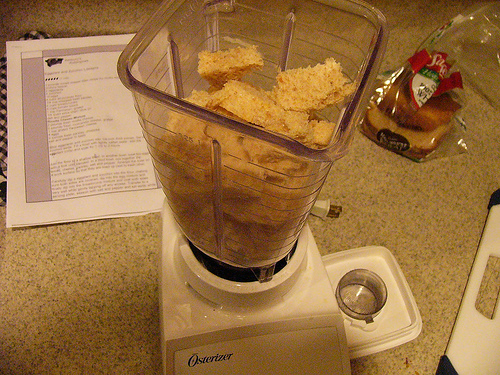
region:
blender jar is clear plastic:
[118, 1, 393, 282]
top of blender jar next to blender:
[319, 243, 424, 361]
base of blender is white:
[158, 196, 352, 373]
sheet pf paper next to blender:
[4, 32, 169, 228]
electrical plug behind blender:
[311, 199, 344, 223]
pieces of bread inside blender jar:
[163, 44, 360, 146]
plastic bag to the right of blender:
[358, 10, 495, 159]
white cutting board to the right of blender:
[432, 186, 499, 373]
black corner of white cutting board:
[432, 355, 455, 374]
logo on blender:
[184, 350, 237, 367]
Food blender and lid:
[141, 209, 408, 344]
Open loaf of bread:
[393, 47, 491, 179]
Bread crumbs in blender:
[277, 37, 375, 149]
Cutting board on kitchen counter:
[424, 175, 499, 316]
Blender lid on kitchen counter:
[330, 232, 422, 342]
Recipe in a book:
[2, 26, 115, 205]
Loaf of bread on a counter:
[400, 92, 484, 181]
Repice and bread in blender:
[16, 8, 281, 350]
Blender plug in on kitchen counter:
[308, 188, 361, 229]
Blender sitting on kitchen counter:
[113, 210, 233, 374]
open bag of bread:
[368, 24, 479, 195]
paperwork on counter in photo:
[11, 13, 173, 275]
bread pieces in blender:
[105, 23, 425, 348]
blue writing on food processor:
[159, 307, 344, 373]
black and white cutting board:
[417, 179, 495, 370]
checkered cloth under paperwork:
[3, 24, 119, 289]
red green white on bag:
[409, 16, 469, 193]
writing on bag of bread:
[383, 21, 455, 189]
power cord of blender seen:
[233, 174, 393, 257]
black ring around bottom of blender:
[111, 206, 336, 301]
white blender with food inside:
[112, 5, 352, 373]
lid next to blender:
[120, 4, 430, 371]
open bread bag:
[368, 14, 499, 164]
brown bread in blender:
[117, 13, 389, 266]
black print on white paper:
[5, 22, 169, 247]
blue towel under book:
[0, 19, 118, 239]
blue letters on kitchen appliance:
[148, 320, 295, 371]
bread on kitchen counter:
[358, 31, 495, 242]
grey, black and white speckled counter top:
[0, 227, 151, 357]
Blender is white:
[110, 0, 398, 370]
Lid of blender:
[323, 231, 428, 364]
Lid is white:
[318, 240, 428, 362]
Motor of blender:
[147, 193, 353, 371]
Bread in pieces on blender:
[188, 35, 360, 138]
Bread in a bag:
[357, 26, 478, 172]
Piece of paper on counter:
[2, 30, 178, 236]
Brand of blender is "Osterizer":
[150, 245, 345, 370]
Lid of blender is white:
[316, 240, 427, 361]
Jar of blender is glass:
[104, 1, 394, 277]